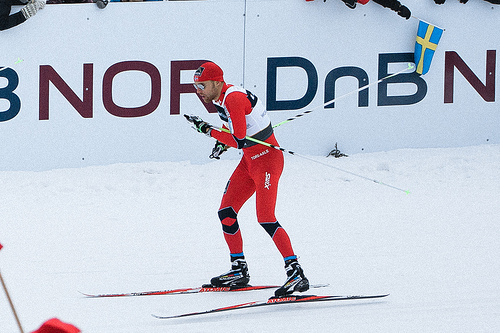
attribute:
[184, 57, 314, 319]
uniform — red, white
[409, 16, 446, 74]
flag — yellow and blue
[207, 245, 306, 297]
boots — black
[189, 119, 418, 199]
ski pole — black and white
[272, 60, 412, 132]
ski pole — black and white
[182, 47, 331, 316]
man — wearing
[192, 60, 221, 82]
hat — red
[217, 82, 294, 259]
snowsuit — red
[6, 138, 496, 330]
snow — white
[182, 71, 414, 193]
sticks — white and black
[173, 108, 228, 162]
gloves — black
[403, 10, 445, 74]
flag — blue and yellow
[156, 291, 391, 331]
ski — red, white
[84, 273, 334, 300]
ski — red, white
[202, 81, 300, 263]
outfit — red, black, and white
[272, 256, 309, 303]
boot — black, white, blue, and red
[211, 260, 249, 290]
boot — black, white, blue, and red